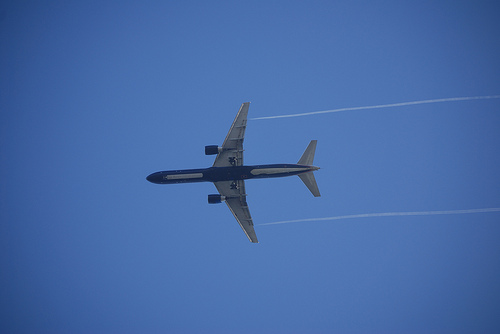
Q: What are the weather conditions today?
A: It is clear.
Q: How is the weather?
A: It is clear.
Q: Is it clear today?
A: Yes, it is clear.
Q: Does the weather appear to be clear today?
A: Yes, it is clear.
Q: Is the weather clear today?
A: Yes, it is clear.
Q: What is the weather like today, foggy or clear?
A: It is clear.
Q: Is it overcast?
A: No, it is clear.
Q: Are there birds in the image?
A: No, there are no birds.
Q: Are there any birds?
A: No, there are no birds.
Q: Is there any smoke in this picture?
A: Yes, there is smoke.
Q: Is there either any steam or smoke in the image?
A: Yes, there is smoke.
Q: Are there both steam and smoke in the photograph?
A: No, there is smoke but no steam.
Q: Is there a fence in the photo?
A: No, there are no fences.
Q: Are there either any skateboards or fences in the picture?
A: No, there are no fences or skateboards.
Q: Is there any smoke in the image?
A: Yes, there is smoke.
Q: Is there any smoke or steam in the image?
A: Yes, there is smoke.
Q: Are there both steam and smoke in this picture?
A: No, there is smoke but no steam.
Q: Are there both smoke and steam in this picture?
A: No, there is smoke but no steam.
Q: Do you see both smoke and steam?
A: No, there is smoke but no steam.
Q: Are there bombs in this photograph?
A: No, there are no bombs.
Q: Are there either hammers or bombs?
A: No, there are no bombs or hammers.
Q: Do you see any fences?
A: No, there are no fences.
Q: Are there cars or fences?
A: No, there are no fences or cars.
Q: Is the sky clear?
A: Yes, the sky is clear.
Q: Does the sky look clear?
A: Yes, the sky is clear.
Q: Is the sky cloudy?
A: No, the sky is clear.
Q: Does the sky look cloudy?
A: No, the sky is clear.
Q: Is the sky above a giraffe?
A: No, the sky is above the airplane.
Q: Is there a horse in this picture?
A: No, there are no horses.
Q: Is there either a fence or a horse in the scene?
A: No, there are no horses or fences.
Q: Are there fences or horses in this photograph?
A: No, there are no horses or fences.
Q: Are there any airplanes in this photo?
A: Yes, there is an airplane.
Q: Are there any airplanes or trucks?
A: Yes, there is an airplane.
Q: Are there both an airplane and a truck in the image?
A: No, there is an airplane but no trucks.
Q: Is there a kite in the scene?
A: No, there are no kites.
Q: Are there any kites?
A: No, there are no kites.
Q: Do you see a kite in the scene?
A: No, there are no kites.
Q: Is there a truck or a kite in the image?
A: No, there are no kites or trucks.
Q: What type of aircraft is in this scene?
A: The aircraft is an airplane.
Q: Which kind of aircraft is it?
A: The aircraft is an airplane.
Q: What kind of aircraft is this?
A: This is an airplane.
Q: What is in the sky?
A: The airplane is in the sky.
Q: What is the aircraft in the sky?
A: The aircraft is an airplane.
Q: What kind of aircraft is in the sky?
A: The aircraft is an airplane.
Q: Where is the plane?
A: The plane is in the sky.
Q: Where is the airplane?
A: The plane is in the sky.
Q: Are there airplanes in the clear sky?
A: Yes, there is an airplane in the sky.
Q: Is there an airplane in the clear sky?
A: Yes, there is an airplane in the sky.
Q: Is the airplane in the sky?
A: Yes, the airplane is in the sky.